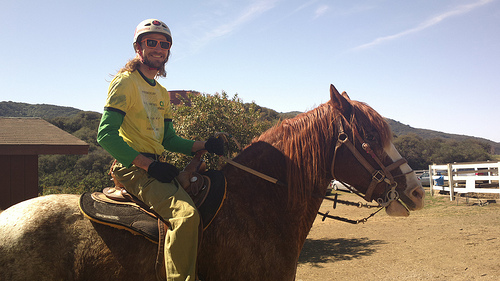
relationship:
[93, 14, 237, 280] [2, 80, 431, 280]
man on horse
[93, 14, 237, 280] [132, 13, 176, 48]
man wearing helmet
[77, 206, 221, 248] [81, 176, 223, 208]
blanket under saddle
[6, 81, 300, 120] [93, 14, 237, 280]
mountains near man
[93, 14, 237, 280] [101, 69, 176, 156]
man in shirt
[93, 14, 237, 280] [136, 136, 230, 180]
man wears gloves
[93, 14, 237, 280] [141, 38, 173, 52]
man wearing glasses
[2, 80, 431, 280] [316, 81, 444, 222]
horse has head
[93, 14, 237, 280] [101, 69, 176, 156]
man wearing shirt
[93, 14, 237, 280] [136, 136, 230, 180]
man has gloves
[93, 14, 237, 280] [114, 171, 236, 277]
man has legs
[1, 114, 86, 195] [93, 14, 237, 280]
building near man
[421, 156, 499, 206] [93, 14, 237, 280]
fence near man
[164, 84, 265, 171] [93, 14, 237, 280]
bush near man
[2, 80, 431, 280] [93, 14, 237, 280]
horse under man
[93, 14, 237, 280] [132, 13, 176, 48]
man in helmet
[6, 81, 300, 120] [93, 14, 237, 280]
mountains behind man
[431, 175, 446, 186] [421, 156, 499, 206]
bin on fence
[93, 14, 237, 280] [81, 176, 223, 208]
man on saddle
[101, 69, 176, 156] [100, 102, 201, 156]
shirt has sleeves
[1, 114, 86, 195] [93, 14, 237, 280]
building behind man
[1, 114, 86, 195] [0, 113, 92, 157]
building has roof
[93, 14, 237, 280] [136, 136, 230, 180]
man in gloves